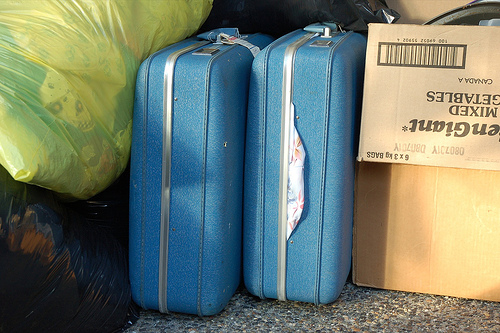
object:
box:
[353, 22, 500, 174]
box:
[350, 157, 498, 305]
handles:
[193, 22, 352, 62]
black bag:
[0, 165, 142, 333]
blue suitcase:
[124, 27, 273, 317]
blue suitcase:
[242, 20, 366, 306]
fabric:
[282, 101, 306, 239]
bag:
[0, 0, 214, 201]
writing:
[366, 36, 500, 166]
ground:
[119, 282, 497, 332]